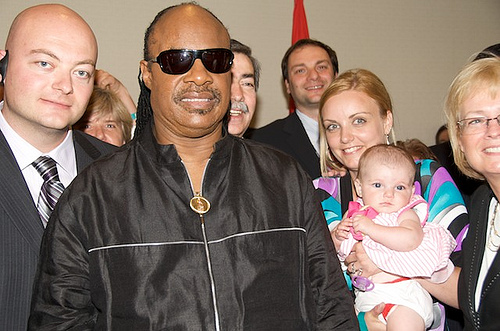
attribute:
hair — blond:
[441, 60, 499, 174]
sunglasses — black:
[132, 26, 269, 75]